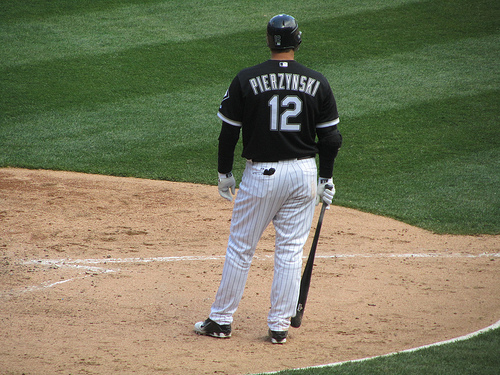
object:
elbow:
[319, 130, 346, 150]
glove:
[312, 176, 334, 206]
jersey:
[214, 57, 341, 180]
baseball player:
[189, 11, 346, 343]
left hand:
[217, 172, 235, 201]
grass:
[0, 0, 499, 374]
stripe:
[326, 36, 498, 114]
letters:
[247, 70, 324, 95]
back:
[237, 59, 326, 162]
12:
[267, 92, 304, 135]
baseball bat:
[291, 183, 335, 328]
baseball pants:
[207, 159, 320, 331]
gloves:
[216, 174, 240, 202]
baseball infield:
[254, 207, 499, 373]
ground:
[0, 166, 499, 374]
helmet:
[264, 12, 306, 51]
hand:
[215, 172, 239, 203]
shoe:
[191, 315, 235, 338]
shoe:
[265, 322, 291, 345]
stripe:
[263, 182, 269, 216]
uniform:
[209, 60, 342, 331]